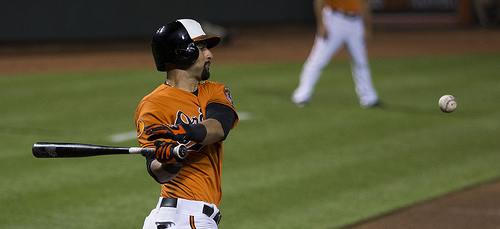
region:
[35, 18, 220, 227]
the man hits the ball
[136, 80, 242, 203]
the man has an orange uniform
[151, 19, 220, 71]
the man is wearing a helmet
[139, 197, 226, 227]
the man has white pants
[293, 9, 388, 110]
the man is walking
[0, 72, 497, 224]
the grass is green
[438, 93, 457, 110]
the ball is in the air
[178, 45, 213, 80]
the man has a serious face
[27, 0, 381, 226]
there are two men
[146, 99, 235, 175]
the man has a black shirt under his uniform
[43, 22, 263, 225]
The man is swinging the bat.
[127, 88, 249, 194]
The man has on a orange jersey.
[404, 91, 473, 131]
The ball is in the air.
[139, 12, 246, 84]
The man is wearing a black and white helmet.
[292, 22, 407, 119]
The man is wearing white pants.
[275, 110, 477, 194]
The grass is green.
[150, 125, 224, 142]
The man is wearing orange and black gloves.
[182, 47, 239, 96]
The man has facial hair.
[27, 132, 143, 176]
The bat is black.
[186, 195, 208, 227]
The pants have an orange stripe on the side.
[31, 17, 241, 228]
batter holding black bat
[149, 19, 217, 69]
black white and orange plastic helmet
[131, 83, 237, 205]
black white and orange baseball jersey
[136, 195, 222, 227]
black white and orange baseball pants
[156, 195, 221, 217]
black belt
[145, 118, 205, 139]
orange and black baseball glove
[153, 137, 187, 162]
orange and black baseball glove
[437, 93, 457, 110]
dirty white baseball with red stitching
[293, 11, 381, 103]
white baseball pants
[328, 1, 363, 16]
orange baseball jersey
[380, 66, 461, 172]
A baseball in flight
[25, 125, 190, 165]
A black baseball bat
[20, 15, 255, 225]
A player swinging a bat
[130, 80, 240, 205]
An orange baseball jersey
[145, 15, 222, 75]
A batting helmet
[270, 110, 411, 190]
A patch of green grass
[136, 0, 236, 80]
A face with a beard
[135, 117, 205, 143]
A black and orange batting glove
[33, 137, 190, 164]
bat is black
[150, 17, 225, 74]
helmet is black and white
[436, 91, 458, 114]
ball is traveling in the air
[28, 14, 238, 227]
player is swinging his bat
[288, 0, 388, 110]
another player is in the background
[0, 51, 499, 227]
green field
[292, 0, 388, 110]
player is wearing white pants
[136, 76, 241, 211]
player is wearing an orange shirt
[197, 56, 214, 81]
player has a beard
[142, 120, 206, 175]
player is wearing orange and black gloves